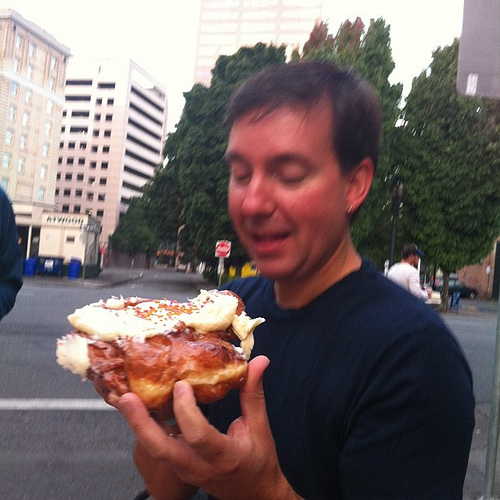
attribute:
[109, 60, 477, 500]
man — smiling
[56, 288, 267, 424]
food — brown, white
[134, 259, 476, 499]
shirt — black, blue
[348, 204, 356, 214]
earring — silver, small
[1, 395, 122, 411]
traffic line — white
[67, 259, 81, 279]
trash bin — blue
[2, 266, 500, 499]
street — gray, empty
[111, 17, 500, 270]
leaves — green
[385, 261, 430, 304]
shirt — white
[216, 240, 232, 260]
stop sign — red, white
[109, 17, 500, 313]
trees — fluffy, green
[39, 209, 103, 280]
building — white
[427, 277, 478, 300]
car — parked, black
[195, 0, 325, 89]
building — tall, white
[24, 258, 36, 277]
trash bin — blue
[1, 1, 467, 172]
sky — white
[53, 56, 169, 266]
building — white